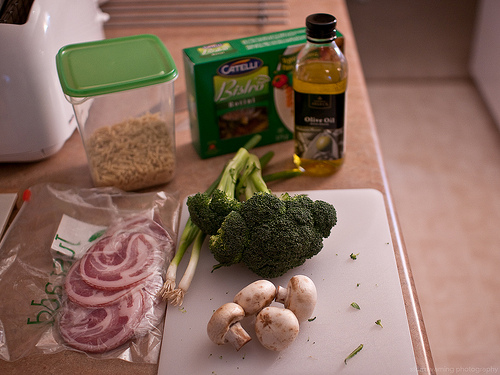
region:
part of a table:
[401, 256, 406, 265]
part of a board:
[350, 308, 360, 324]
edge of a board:
[367, 277, 373, 300]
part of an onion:
[261, 279, 265, 291]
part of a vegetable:
[275, 246, 285, 265]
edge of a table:
[403, 249, 423, 281]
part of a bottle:
[326, 155, 335, 180]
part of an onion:
[289, 330, 292, 337]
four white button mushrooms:
[204, 274, 318, 353]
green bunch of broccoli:
[187, 150, 337, 272]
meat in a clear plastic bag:
[5, 183, 165, 360]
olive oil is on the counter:
[291, 12, 348, 179]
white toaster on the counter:
[2, 0, 107, 162]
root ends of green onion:
[162, 218, 207, 308]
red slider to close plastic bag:
[20, 187, 31, 202]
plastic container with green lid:
[52, 31, 182, 188]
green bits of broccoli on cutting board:
[340, 250, 385, 365]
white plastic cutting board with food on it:
[153, 187, 415, 374]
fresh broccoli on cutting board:
[186, 142, 350, 274]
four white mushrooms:
[192, 280, 331, 354]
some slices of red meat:
[25, 196, 163, 372]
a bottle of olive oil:
[281, 18, 363, 185]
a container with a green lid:
[54, 28, 187, 193]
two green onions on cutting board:
[161, 142, 286, 315]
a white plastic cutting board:
[142, 168, 468, 373]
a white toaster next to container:
[4, 0, 114, 171]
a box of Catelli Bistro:
[179, 19, 376, 169]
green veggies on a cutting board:
[169, 123, 357, 313]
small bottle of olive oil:
[286, 5, 381, 205]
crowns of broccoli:
[183, 139, 360, 275]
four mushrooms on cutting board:
[200, 267, 352, 368]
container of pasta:
[47, 30, 191, 205]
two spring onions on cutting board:
[117, 145, 249, 324]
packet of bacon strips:
[20, 184, 197, 374]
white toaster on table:
[2, 0, 130, 178]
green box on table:
[179, 31, 366, 166]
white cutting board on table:
[147, 175, 459, 374]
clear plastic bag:
[13, 160, 182, 374]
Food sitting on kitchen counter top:
[7, 10, 490, 362]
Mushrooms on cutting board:
[200, 273, 335, 363]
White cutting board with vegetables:
[153, 180, 415, 373]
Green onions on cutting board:
[165, 220, 206, 305]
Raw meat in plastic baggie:
[35, 205, 163, 364]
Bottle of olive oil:
[285, 9, 357, 179]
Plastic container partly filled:
[56, 35, 186, 192]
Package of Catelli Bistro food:
[190, 31, 367, 158]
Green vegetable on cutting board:
[207, 185, 349, 271]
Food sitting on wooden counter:
[8, 18, 429, 368]